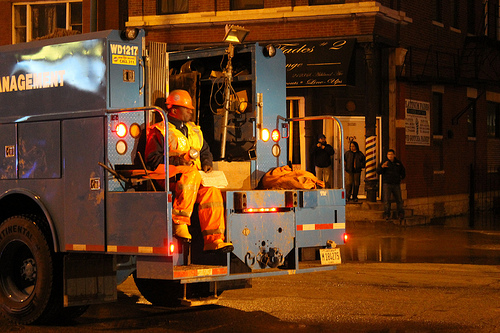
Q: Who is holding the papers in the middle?
A: The man is holding the papers.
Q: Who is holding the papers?
A: The man is holding the papers.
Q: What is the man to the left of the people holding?
A: The man is holding the papers.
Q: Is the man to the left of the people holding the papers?
A: Yes, the man is holding the papers.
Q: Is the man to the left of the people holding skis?
A: No, the man is holding the papers.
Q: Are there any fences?
A: No, there are no fences.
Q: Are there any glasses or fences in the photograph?
A: No, there are no fences or glasses.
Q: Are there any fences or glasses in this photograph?
A: No, there are no fences or glasses.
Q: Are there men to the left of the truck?
A: No, the man is to the right of the truck.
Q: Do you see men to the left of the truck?
A: No, the man is to the right of the truck.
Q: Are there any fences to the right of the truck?
A: No, there is a man to the right of the truck.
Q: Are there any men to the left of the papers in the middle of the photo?
A: No, the man is to the right of the papers.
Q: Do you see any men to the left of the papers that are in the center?
A: No, the man is to the right of the papers.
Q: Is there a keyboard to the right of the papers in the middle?
A: No, there is a man to the right of the papers.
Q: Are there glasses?
A: No, there are no glasses.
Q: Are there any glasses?
A: No, there are no glasses.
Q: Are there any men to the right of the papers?
A: Yes, there is a man to the right of the papers.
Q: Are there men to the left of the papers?
A: No, the man is to the right of the papers.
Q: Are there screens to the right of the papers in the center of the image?
A: No, there is a man to the right of the papers.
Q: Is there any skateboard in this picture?
A: No, there are no skateboards.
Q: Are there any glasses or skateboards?
A: No, there are no skateboards or glasses.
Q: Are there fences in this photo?
A: No, there are no fences.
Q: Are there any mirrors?
A: No, there are no mirrors.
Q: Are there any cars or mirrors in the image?
A: No, there are no mirrors or cars.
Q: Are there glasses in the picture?
A: No, there are no glasses.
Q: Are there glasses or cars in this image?
A: No, there are no glasses or cars.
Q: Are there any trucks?
A: Yes, there is a truck.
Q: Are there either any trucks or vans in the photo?
A: Yes, there is a truck.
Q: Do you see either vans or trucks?
A: Yes, there is a truck.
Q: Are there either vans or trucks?
A: Yes, there is a truck.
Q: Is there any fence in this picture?
A: No, there are no fences.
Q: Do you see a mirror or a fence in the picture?
A: No, there are no fences or mirrors.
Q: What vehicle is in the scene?
A: The vehicle is a truck.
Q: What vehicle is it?
A: The vehicle is a truck.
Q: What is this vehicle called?
A: That is a truck.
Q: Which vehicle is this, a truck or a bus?
A: That is a truck.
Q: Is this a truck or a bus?
A: This is a truck.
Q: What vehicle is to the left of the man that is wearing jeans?
A: The vehicle is a truck.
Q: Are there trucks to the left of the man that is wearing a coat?
A: Yes, there is a truck to the left of the man.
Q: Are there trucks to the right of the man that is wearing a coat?
A: No, the truck is to the left of the man.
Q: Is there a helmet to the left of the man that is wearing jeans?
A: No, there is a truck to the left of the man.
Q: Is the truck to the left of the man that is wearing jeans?
A: Yes, the truck is to the left of the man.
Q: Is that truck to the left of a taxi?
A: No, the truck is to the left of the man.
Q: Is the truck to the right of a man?
A: No, the truck is to the left of a man.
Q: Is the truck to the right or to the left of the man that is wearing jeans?
A: The truck is to the left of the man.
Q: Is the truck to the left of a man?
A: Yes, the truck is to the left of a man.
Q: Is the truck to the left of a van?
A: No, the truck is to the left of a man.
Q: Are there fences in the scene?
A: No, there are no fences.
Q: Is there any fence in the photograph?
A: No, there are no fences.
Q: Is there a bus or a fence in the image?
A: No, there are no fences or buses.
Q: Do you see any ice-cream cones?
A: No, there are no ice-cream cones.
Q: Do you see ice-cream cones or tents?
A: No, there are no ice-cream cones or tents.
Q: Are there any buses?
A: No, there are no buses.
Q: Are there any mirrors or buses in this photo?
A: No, there are no buses or mirrors.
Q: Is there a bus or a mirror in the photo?
A: No, there are no buses or mirrors.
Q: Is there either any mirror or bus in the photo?
A: No, there are no buses or mirrors.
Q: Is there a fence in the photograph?
A: No, there are no fences.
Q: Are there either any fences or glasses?
A: No, there are no fences or glasses.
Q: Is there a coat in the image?
A: Yes, there is a coat.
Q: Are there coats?
A: Yes, there is a coat.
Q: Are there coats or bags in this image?
A: Yes, there is a coat.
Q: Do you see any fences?
A: No, there are no fences.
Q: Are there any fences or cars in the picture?
A: No, there are no fences or cars.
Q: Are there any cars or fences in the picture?
A: No, there are no fences or cars.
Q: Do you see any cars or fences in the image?
A: No, there are no fences or cars.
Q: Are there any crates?
A: No, there are no crates.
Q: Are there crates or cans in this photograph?
A: No, there are no crates or cans.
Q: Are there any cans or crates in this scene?
A: No, there are no crates or cans.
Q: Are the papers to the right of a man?
A: No, the papers are to the left of a man.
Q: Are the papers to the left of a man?
A: Yes, the papers are to the left of a man.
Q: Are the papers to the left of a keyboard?
A: No, the papers are to the left of a man.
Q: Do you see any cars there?
A: No, there are no cars.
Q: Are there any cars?
A: No, there are no cars.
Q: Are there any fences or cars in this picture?
A: No, there are no cars or fences.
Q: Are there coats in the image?
A: Yes, there is a coat.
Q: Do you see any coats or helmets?
A: Yes, there is a coat.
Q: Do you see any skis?
A: No, there are no skis.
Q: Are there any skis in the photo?
A: No, there are no skis.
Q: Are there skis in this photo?
A: No, there are no skis.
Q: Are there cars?
A: No, there are no cars.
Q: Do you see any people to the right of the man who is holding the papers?
A: Yes, there are people to the right of the man.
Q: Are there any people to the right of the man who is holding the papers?
A: Yes, there are people to the right of the man.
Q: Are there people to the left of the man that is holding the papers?
A: No, the people are to the right of the man.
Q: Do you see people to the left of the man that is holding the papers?
A: No, the people are to the right of the man.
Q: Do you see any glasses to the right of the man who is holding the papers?
A: No, there are people to the right of the man.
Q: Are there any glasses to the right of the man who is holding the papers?
A: No, there are people to the right of the man.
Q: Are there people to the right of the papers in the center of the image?
A: Yes, there are people to the right of the papers.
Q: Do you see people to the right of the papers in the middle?
A: Yes, there are people to the right of the papers.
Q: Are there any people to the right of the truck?
A: Yes, there are people to the right of the truck.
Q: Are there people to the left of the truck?
A: No, the people are to the right of the truck.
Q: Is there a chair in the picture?
A: No, there are no chairs.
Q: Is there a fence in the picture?
A: No, there are no fences.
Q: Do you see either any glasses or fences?
A: No, there are no fences or glasses.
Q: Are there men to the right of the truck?
A: Yes, there is a man to the right of the truck.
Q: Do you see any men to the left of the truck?
A: No, the man is to the right of the truck.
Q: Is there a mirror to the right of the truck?
A: No, there is a man to the right of the truck.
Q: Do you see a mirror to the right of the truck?
A: No, there is a man to the right of the truck.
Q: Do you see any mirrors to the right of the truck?
A: No, there is a man to the right of the truck.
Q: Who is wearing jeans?
A: The man is wearing jeans.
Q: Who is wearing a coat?
A: The man is wearing a coat.